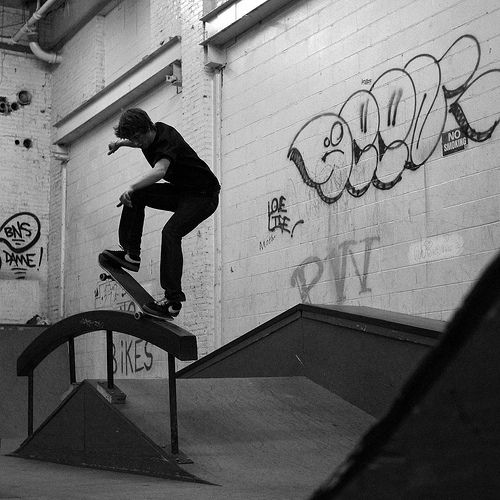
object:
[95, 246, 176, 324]
board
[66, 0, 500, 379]
wall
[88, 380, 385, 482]
ramp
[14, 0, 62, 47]
pipes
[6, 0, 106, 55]
ceiling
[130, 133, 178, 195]
arm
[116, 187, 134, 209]
hand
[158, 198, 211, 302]
leg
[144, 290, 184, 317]
shoe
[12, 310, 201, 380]
railing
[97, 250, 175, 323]
skateboard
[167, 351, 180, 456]
bar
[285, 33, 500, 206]
graffiti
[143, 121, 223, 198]
shirt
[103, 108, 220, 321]
boy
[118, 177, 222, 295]
pants